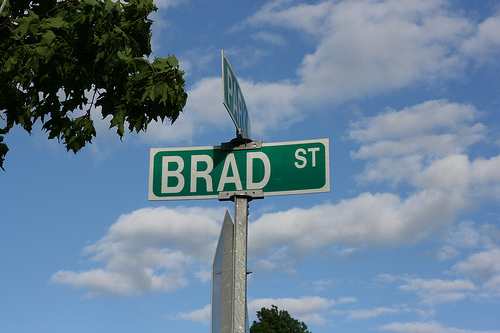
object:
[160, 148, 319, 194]
lettering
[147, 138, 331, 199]
sign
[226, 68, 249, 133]
lettering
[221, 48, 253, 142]
sign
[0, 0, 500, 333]
sky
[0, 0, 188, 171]
tree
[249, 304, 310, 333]
tree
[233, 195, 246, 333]
pole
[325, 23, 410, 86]
clouds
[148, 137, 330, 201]
border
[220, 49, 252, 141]
border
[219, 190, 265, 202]
clasp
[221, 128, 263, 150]
clasp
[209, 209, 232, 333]
sign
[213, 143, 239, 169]
shadow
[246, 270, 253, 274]
bolt